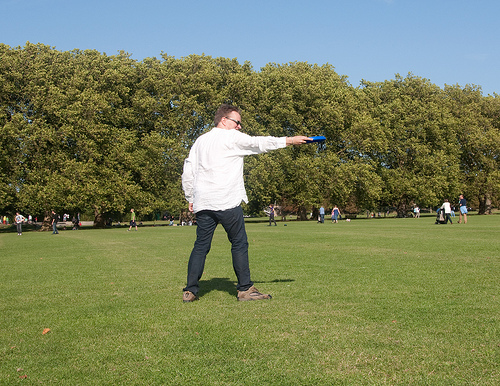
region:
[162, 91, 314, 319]
Man wearing white long sleeve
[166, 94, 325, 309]
Man wearing blue jeans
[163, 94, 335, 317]
Man holds a frisbee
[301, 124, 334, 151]
Frisbee is blue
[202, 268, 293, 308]
Shadow of man cast in the grass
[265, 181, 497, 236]
People walking in the park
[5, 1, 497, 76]
Ski is blue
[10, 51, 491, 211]
Tall trees in the park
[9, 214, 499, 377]
Field is covered with green grass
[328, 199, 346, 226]
Woman wearing a blue dress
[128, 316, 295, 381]
the grass is green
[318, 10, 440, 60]
the sky is blue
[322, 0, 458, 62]
the sky is clear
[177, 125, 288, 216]
the shirt is white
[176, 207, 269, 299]
the pants are black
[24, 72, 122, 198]
the trees are green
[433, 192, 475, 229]
the people are standing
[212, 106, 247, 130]
the man is wearing black glasses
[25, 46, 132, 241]
the trees are tall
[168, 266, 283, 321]
the man has shoes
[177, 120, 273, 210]
a white shirt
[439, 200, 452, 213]
a white shirt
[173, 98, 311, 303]
a person in a field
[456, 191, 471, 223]
a person in a field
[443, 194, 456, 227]
a person in a field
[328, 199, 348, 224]
a person in a field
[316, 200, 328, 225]
a person in a field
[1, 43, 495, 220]
many green trees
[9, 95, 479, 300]
many people in a field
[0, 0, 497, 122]
the blue sky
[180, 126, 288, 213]
long sleeve white shirt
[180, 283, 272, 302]
brown tennis-shoes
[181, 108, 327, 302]
man throwing blue frisbee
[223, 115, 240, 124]
black sun glasses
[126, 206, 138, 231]
person wearing green shirt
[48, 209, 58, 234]
person wearing black shirt and blue jeans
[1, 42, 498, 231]
big green trees in a line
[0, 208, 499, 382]
manicured green grass park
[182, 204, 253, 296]
pair of dark blue jeans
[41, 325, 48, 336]
brown leaf on green grass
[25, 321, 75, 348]
orange object on grass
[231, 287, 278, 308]
brown shoes on man's foot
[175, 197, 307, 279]
crinkled blue jeans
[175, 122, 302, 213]
white long sleeve shirt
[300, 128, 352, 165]
hand holding blue frisbee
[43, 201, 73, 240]
man standing by tree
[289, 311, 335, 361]
bald spot on green grass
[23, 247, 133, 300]
well manicured green grass in park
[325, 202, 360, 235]
woman wearing blue sun dress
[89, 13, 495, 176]
large cluster of green trees